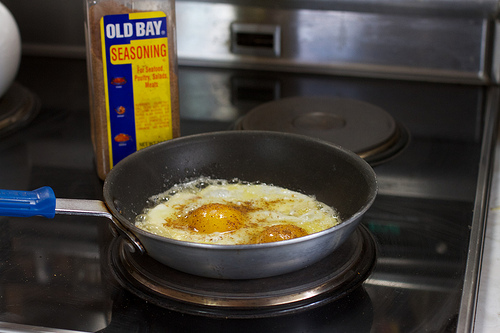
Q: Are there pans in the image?
A: Yes, there is a pan.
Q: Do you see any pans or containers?
A: Yes, there is a pan.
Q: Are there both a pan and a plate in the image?
A: Yes, there are both a pan and a plate.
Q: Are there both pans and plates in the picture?
A: Yes, there are both a pan and a plate.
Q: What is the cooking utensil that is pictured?
A: The cooking utensil is a pan.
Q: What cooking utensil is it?
A: The cooking utensil is a pan.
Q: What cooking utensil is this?
A: This is a pan.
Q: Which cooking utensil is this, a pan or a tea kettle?
A: This is a pan.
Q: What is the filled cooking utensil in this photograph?
A: The cooking utensil is a pan.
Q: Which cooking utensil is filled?
A: The cooking utensil is a pan.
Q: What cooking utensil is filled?
A: The cooking utensil is a pan.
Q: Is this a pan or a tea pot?
A: This is a pan.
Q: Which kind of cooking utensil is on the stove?
A: The cooking utensil is a pan.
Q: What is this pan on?
A: The pan is on the stove.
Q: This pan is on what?
A: The pan is on the stove.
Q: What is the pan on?
A: The pan is on the stove.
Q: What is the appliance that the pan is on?
A: The appliance is a stove.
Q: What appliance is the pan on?
A: The pan is on the stove.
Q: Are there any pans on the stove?
A: Yes, there is a pan on the stove.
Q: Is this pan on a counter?
A: No, the pan is on the stove.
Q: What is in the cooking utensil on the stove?
A: The eggs are in the pan.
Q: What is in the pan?
A: The eggs are in the pan.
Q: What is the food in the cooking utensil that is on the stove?
A: The food is eggs.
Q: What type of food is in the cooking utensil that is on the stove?
A: The food is eggs.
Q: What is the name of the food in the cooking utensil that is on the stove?
A: The food is eggs.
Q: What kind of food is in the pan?
A: The food is eggs.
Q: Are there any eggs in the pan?
A: Yes, there are eggs in the pan.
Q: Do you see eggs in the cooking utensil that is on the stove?
A: Yes, there are eggs in the pan.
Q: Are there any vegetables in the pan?
A: No, there are eggs in the pan.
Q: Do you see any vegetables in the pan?
A: No, there are eggs in the pan.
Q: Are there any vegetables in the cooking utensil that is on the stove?
A: No, there are eggs in the pan.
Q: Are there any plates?
A: Yes, there is a plate.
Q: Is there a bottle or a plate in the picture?
A: Yes, there is a plate.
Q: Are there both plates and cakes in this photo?
A: No, there is a plate but no cakes.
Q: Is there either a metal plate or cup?
A: Yes, there is a metal plate.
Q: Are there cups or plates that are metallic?
A: Yes, the plate is metallic.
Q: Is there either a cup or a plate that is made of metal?
A: Yes, the plate is made of metal.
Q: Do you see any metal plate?
A: Yes, there is a metal plate.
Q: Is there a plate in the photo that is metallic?
A: Yes, there is a plate that is metallic.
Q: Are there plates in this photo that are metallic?
A: Yes, there is a plate that is metallic.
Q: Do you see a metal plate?
A: Yes, there is a plate that is made of metal.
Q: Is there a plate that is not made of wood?
A: Yes, there is a plate that is made of metal.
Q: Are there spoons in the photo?
A: No, there are no spoons.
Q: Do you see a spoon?
A: No, there are no spoons.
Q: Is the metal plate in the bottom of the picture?
A: Yes, the plate is in the bottom of the image.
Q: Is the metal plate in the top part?
A: No, the plate is in the bottom of the image.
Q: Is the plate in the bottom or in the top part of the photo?
A: The plate is in the bottom of the image.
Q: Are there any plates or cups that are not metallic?
A: No, there is a plate but it is metallic.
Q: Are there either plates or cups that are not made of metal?
A: No, there is a plate but it is made of metal.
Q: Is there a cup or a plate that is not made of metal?
A: No, there is a plate but it is made of metal.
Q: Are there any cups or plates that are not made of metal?
A: No, there is a plate but it is made of metal.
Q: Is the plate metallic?
A: Yes, the plate is metallic.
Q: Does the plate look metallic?
A: Yes, the plate is metallic.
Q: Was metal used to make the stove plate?
A: Yes, the plate is made of metal.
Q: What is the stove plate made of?
A: The plate is made of metal.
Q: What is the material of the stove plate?
A: The plate is made of metal.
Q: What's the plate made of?
A: The plate is made of metal.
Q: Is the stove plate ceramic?
A: No, the plate is metallic.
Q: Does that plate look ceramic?
A: No, the plate is metallic.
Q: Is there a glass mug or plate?
A: No, there is a plate but it is metallic.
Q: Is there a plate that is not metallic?
A: No, there is a plate but it is metallic.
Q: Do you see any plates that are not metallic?
A: No, there is a plate but it is metallic.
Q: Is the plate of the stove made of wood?
A: No, the plate is made of metal.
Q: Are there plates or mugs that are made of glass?
A: No, there is a plate but it is made of metal.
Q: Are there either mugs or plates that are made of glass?
A: No, there is a plate but it is made of metal.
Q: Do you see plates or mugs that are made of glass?
A: No, there is a plate but it is made of metal.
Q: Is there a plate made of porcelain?
A: No, there is a plate but it is made of metal.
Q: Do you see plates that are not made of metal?
A: No, there is a plate but it is made of metal.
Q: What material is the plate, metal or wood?
A: The plate is made of metal.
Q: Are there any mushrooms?
A: No, there are no mushrooms.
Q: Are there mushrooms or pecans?
A: No, there are no mushrooms or pecans.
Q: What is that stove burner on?
A: The stove burner is on the stove.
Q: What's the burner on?
A: The stove burner is on the stove.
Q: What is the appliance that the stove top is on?
A: The appliance is a stove.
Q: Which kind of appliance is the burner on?
A: The stove top is on the stove.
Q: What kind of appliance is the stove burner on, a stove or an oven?
A: The stove burner is on a stove.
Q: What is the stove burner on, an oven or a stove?
A: The stove burner is on a stove.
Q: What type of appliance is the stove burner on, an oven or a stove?
A: The stove burner is on a stove.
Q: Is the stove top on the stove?
A: Yes, the stove top is on the stove.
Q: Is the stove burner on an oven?
A: No, the stove burner is on the stove.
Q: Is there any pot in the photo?
A: No, there are no pots.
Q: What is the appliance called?
A: The appliance is a stove.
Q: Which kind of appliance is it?
A: The appliance is a stove.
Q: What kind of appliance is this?
A: This is a stove.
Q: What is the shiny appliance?
A: The appliance is a stove.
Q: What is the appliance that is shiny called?
A: The appliance is a stove.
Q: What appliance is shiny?
A: The appliance is a stove.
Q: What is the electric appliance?
A: The appliance is a stove.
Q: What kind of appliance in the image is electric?
A: The appliance is a stove.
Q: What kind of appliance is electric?
A: The appliance is a stove.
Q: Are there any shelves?
A: No, there are no shelves.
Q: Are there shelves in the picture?
A: No, there are no shelves.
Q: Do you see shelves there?
A: No, there are no shelves.